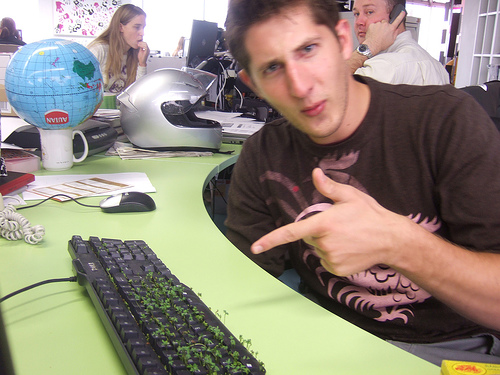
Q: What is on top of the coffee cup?
A: Globe.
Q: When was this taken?
A: Daytime.